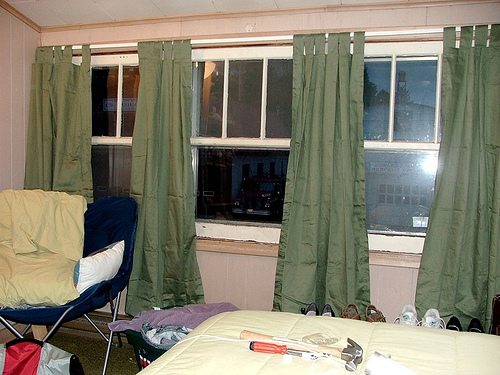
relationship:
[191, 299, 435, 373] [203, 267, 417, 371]
comforter on bed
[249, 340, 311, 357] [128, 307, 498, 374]
screwdriver on a bed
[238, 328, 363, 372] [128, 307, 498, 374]
hammer on a bed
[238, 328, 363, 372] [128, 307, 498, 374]
hammer on bed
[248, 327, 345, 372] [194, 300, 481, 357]
hammer on bed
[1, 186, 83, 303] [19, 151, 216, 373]
blanket on chairs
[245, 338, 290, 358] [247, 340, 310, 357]
hand of chissel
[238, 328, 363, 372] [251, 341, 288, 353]
hammer with redhandle